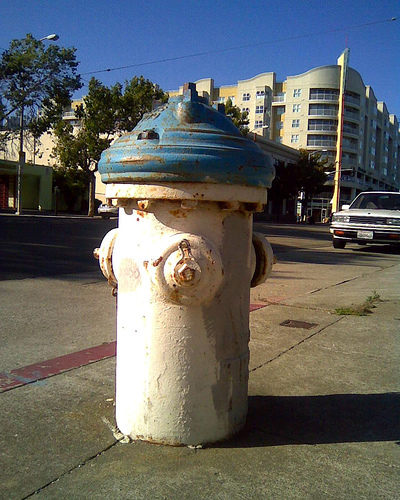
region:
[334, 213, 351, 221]
the white headlight of the car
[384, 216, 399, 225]
the white headlight of the car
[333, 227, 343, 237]
the orange headlight of the car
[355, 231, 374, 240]
the white license plate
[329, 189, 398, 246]
the white car parked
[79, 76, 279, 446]
the blue and white fire hydrant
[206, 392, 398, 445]
the shadow on the ground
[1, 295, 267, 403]
the red curbing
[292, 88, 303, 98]
the window of the building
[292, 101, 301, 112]
the window of the building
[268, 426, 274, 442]
part of a shadow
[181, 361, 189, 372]
edge of a pole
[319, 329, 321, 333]
part of a plate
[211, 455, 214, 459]
side of a pillar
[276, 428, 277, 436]
edge of a path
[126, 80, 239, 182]
top of plug is blue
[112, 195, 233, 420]
yellow body of plug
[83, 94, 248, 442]
fire plug on sidewalk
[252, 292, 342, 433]
sidewalk is dark grey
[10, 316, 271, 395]
red plate on sidewalk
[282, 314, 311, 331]
brown cover on sidewalk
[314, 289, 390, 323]
small plants on sidewalk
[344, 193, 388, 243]
white truck is parked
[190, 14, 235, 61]
blue and clear sky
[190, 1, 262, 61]
no clouds in sky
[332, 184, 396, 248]
car is parked on side of road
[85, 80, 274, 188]
top of hydrant is blue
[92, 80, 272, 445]
rusty spots on hydrant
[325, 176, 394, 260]
the car is white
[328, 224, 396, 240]
orange lights on car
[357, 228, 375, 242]
white plate on car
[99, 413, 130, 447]
white paint on ground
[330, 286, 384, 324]
grass growing in concrete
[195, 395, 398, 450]
shadow of hydrant on ground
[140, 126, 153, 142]
black part on hydrant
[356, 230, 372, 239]
license plate on the car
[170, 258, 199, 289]
lug nut on the fire hydrant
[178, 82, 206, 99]
lug nut on the fire hydrant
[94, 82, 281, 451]
fire hydrant on the ground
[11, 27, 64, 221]
lamp on the sidewalk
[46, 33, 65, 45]
light fixture on the pole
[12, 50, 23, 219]
pole attached to the lamp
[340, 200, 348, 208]
side mirror on the car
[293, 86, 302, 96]
window on the building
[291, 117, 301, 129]
window on the building